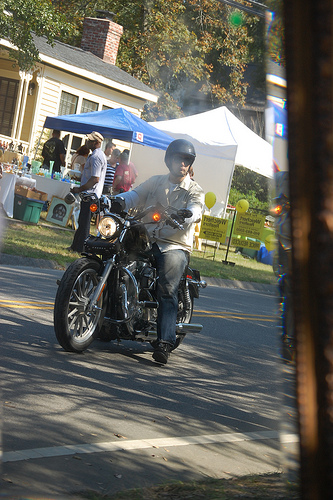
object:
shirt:
[41, 137, 66, 172]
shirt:
[113, 163, 136, 191]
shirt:
[104, 159, 120, 187]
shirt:
[109, 172, 205, 266]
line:
[0, 299, 280, 322]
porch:
[0, 59, 39, 145]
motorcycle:
[53, 191, 207, 352]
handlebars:
[89, 200, 185, 233]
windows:
[58, 130, 132, 169]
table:
[25, 168, 79, 205]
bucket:
[14, 192, 47, 224]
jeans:
[129, 243, 190, 348]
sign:
[135, 131, 143, 142]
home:
[0, 8, 162, 179]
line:
[0, 429, 301, 464]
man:
[95, 138, 205, 365]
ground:
[0, 215, 277, 500]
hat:
[86, 131, 105, 143]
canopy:
[147, 105, 275, 180]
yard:
[0, 99, 278, 283]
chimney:
[80, 9, 123, 65]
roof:
[2, 10, 161, 97]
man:
[62, 130, 107, 254]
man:
[113, 152, 136, 196]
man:
[42, 129, 66, 173]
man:
[102, 149, 121, 195]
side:
[0, 246, 280, 289]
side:
[0, 466, 301, 500]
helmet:
[164, 139, 196, 177]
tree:
[0, 0, 262, 121]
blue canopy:
[43, 107, 176, 150]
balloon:
[204, 192, 249, 214]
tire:
[54, 255, 109, 353]